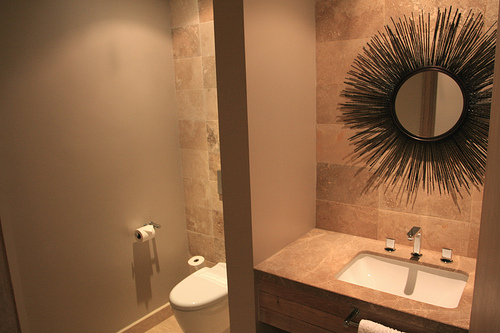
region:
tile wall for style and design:
[183, 73, 210, 145]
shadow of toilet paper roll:
[131, 243, 158, 312]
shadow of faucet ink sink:
[401, 263, 421, 290]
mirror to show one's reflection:
[402, 74, 454, 133]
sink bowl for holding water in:
[337, 248, 467, 308]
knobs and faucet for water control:
[382, 228, 454, 262]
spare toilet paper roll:
[183, 253, 209, 269]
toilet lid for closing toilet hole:
[176, 264, 225, 311]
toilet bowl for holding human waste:
[168, 313, 233, 331]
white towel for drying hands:
[358, 318, 392, 332]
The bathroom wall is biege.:
[35, 77, 130, 190]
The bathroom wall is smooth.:
[32, 80, 113, 210]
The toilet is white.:
[168, 258, 228, 328]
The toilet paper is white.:
[184, 250, 211, 270]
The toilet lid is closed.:
[162, 262, 232, 330]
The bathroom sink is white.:
[359, 260, 452, 302]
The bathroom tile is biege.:
[320, 186, 382, 236]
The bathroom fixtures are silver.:
[384, 224, 456, 262]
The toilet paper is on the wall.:
[129, 220, 161, 242]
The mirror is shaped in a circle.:
[392, 64, 468, 142]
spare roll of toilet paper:
[185, 254, 204, 268]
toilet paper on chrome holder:
[133, 221, 161, 243]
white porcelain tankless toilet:
[167, 261, 230, 331]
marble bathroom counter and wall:
[174, 1, 499, 331]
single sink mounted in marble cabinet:
[255, 227, 475, 331]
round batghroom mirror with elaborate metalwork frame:
[339, 6, 499, 199]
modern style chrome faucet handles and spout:
[383, 224, 453, 269]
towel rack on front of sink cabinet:
[348, 307, 409, 331]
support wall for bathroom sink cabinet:
[214, 0, 316, 331]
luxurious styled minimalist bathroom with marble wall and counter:
[4, 1, 498, 329]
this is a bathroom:
[26, 17, 498, 328]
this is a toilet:
[123, 227, 262, 327]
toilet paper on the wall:
[122, 197, 183, 274]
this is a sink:
[318, 242, 476, 304]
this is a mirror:
[305, 7, 498, 196]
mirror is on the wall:
[310, 2, 497, 217]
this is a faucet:
[372, 210, 457, 261]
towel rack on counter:
[329, 299, 407, 331]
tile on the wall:
[157, 32, 223, 202]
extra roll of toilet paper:
[165, 238, 214, 275]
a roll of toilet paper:
[137, 223, 157, 242]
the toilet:
[161, 261, 243, 325]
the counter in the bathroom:
[278, 210, 458, 325]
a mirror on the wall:
[390, 66, 462, 133]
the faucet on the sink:
[335, 246, 470, 306]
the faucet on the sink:
[380, 225, 456, 261]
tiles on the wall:
[319, 8, 395, 211]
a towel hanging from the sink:
[351, 318, 393, 331]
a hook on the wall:
[150, 219, 160, 227]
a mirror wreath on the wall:
[336, 15, 489, 190]